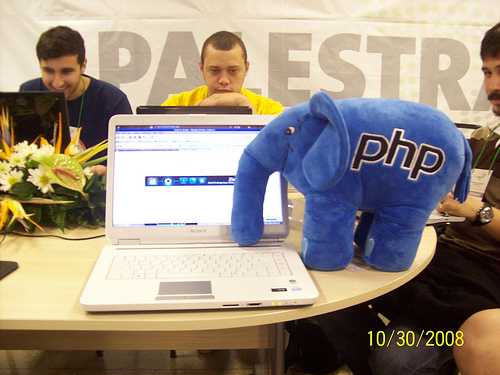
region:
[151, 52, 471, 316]
a blue stuffed elephant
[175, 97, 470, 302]
a stuffed elephant on a table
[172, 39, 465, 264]
a blue stuffed elephant on a table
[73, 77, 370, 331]
a white laptop on a table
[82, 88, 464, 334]
a laptop and elephant on table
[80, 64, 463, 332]
a laptop and elephant next to each other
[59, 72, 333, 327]
a laptop turned on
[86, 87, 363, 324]
a white laptop turned on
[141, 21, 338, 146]
a man wearing a yellow shirt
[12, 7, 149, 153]
a man smiling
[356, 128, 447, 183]
Black and white PHP letters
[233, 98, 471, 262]
Blue stuffed elephant on table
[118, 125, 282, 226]
Browser on screen of laptop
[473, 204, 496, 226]
Flexible watch on mans arm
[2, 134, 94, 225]
Arrangement of flowers on table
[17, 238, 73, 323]
Light brown wooden table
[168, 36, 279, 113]
Man wearing yellow shirt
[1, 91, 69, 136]
Black laptop screen back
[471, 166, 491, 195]
Name tag around mans neck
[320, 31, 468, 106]
Large grey letters on banner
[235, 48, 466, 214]
Stuffed elephant on the table.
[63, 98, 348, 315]
Laptop on the table.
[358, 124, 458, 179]
Logo on the elephant.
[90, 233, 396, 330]
Keyboard on the laptop.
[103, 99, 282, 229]
Screen on the laptop.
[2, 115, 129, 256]
Flowers on the table.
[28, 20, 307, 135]
Men in the background.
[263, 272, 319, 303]
Label on the laptop.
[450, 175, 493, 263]
Watch on the man.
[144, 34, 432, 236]
Man in a yellow shirt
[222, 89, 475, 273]
a stuffed animal on the table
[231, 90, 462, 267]
the animal is blue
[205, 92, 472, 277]
the animal is an elephant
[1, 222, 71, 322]
the table is tan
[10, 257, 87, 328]
the table is made of wood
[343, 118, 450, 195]
letters on the side of the animal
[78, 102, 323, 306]
an open lap top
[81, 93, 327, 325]
the lap top is white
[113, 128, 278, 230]
the screen is on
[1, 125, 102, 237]
flowers on the table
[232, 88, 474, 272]
a blue plush elephant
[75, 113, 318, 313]
a white laptop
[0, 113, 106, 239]
arrangement of flowers on a table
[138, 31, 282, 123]
a man using a laptop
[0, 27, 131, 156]
a man using a laptop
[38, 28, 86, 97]
smiling face of a man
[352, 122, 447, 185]
php on a plush elephant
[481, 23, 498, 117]
the face of a man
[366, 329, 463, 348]
date marker on photo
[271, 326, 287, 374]
metal post for a table